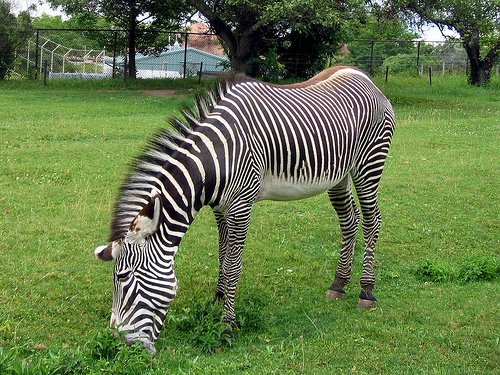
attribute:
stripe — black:
[267, 85, 316, 185]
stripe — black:
[119, 301, 164, 322]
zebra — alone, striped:
[92, 60, 396, 359]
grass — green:
[2, 79, 484, 372]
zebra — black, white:
[76, 65, 394, 334]